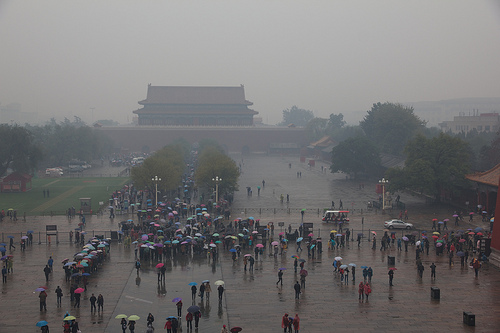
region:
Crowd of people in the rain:
[14, 140, 498, 331]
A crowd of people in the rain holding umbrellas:
[5, 167, 492, 331]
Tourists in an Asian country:
[8, 145, 498, 323]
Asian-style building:
[21, 60, 318, 202]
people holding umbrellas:
[3, 196, 495, 329]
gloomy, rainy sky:
[10, 5, 492, 137]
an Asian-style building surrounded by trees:
[3, 67, 488, 167]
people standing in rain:
[0, 215, 494, 331]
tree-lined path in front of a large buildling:
[88, 131, 268, 232]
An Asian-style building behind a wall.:
[55, 76, 383, 214]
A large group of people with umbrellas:
[132, 198, 262, 270]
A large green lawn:
[30, 177, 120, 213]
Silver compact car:
[381, 215, 417, 229]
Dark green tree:
[401, 127, 478, 205]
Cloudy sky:
[245, 23, 449, 85]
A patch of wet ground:
[235, 274, 275, 311]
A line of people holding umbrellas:
[59, 237, 111, 265]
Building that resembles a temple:
[121, 75, 271, 131]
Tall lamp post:
[147, 167, 167, 213]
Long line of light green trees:
[197, 130, 252, 206]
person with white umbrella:
[213, 274, 232, 291]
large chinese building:
[138, 75, 280, 160]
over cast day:
[359, 35, 484, 97]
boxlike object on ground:
[441, 299, 482, 326]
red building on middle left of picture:
[7, 174, 29, 211]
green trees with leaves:
[155, 144, 196, 194]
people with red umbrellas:
[144, 254, 177, 276]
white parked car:
[384, 216, 419, 234]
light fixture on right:
[370, 172, 403, 222]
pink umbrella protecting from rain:
[271, 234, 285, 256]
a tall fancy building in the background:
[131, 81, 263, 128]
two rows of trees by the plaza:
[135, 140, 233, 200]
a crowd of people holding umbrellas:
[16, 208, 493, 330]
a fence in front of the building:
[96, 121, 318, 158]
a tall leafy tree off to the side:
[363, 95, 434, 149]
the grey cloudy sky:
[1, 4, 495, 121]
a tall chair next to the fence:
[44, 221, 58, 248]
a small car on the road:
[383, 217, 418, 234]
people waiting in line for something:
[61, 235, 107, 277]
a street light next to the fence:
[146, 170, 162, 209]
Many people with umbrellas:
[48, 199, 320, 311]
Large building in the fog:
[129, 76, 268, 159]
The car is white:
[384, 213, 414, 232]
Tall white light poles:
[141, 167, 233, 210]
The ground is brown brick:
[130, 237, 457, 319]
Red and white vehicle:
[312, 201, 359, 232]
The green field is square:
[8, 160, 138, 241]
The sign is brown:
[43, 220, 69, 252]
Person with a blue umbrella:
[179, 274, 205, 307]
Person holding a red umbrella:
[151, 260, 173, 290]